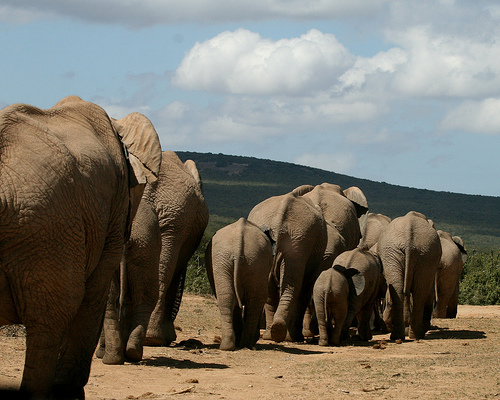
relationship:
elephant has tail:
[202, 214, 273, 359] [230, 238, 252, 317]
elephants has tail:
[376, 210, 437, 343] [397, 231, 417, 300]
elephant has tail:
[250, 191, 332, 349] [271, 238, 285, 307]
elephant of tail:
[310, 267, 355, 351] [319, 282, 334, 326]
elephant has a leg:
[3, 87, 166, 396] [17, 284, 89, 396]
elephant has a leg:
[202, 214, 273, 359] [212, 275, 243, 358]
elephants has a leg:
[376, 210, 437, 343] [408, 278, 437, 341]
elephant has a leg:
[250, 191, 332, 349] [267, 264, 308, 343]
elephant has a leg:
[334, 241, 394, 351] [352, 303, 375, 347]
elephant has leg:
[433, 224, 470, 321] [434, 279, 455, 321]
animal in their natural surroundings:
[202, 214, 273, 359] [7, 95, 498, 399]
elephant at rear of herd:
[3, 87, 166, 396] [7, 95, 498, 399]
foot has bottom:
[267, 264, 308, 343] [267, 318, 291, 348]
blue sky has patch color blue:
[0, 3, 500, 197] [1, 23, 160, 83]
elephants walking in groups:
[4, 88, 471, 400] [7, 95, 498, 399]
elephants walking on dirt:
[4, 88, 471, 400] [4, 281, 499, 400]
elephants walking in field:
[4, 88, 471, 400] [4, 281, 499, 400]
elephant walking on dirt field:
[250, 191, 332, 349] [4, 281, 499, 400]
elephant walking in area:
[433, 224, 470, 321] [4, 281, 499, 400]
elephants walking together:
[4, 88, 471, 400] [7, 95, 498, 399]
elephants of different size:
[4, 88, 471, 400] [7, 95, 498, 399]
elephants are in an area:
[4, 88, 471, 400] [4, 281, 499, 400]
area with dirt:
[202, 214, 273, 359] [4, 281, 499, 400]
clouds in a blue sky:
[161, 23, 494, 130] [2, 3, 499, 111]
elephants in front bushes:
[4, 88, 471, 400] [177, 147, 499, 231]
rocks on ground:
[167, 328, 223, 400] [4, 281, 499, 400]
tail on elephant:
[224, 258, 254, 329] [202, 214, 273, 359]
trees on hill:
[177, 147, 499, 231] [153, 133, 496, 312]